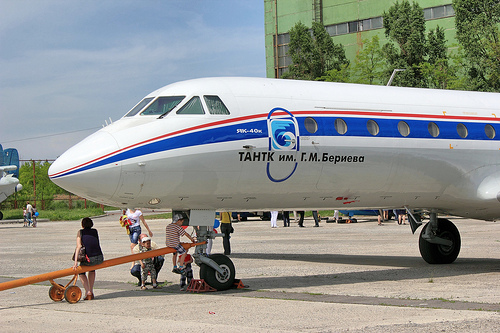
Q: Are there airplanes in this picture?
A: Yes, there is an airplane.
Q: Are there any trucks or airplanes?
A: Yes, there is an airplane.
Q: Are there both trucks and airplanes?
A: No, there is an airplane but no trucks.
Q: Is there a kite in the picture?
A: No, there are no kites.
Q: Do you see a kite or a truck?
A: No, there are no kites or trucks.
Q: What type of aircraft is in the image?
A: The aircraft is an airplane.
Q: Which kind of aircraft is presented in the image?
A: The aircraft is an airplane.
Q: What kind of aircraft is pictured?
A: The aircraft is an airplane.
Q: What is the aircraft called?
A: The aircraft is an airplane.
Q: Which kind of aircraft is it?
A: The aircraft is an airplane.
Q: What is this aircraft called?
A: That is an airplane.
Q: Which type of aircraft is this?
A: That is an airplane.